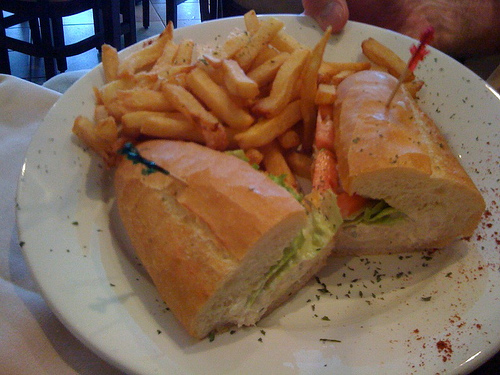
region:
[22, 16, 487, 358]
a sandwich on a plate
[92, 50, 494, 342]
a sandwich cut in half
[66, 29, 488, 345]
french fries next to a sandwich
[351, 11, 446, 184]
a colored toothpick in a sandwich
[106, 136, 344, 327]
lettuce inside of a sandwich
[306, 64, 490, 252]
slices of tomato in a sandwich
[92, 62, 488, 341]
a small baguette cut in half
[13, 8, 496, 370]
a white plate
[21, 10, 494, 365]
a plate with sprinkled herbs and spices on it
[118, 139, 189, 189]
blue plastic on toothpick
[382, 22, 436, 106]
red plastic on toothpick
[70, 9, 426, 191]
french fries on the plate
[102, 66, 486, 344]
sandwich cut in half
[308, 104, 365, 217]
tomatoes on the sandwich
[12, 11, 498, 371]
round white lunch plate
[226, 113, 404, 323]
lettuce on the sandwich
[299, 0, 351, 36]
thumb holding the plate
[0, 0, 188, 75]
legs of chairs behind plate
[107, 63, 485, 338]
white bread sandwich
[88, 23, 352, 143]
french fries on the plate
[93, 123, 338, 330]
sandwich on the plate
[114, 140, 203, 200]
toothpick stuck in a sandwich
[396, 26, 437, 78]
red tag on a toothpick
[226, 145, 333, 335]
lettuce inside of a sandwich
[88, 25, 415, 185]
french fries on a plate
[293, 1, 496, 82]
person holding a plate of food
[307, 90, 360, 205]
tomato on the sandwich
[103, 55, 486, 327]
Sandwich and french fries on a plate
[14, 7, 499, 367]
Sandwich and fries on a white plate.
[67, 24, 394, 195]
Golden french fries on the side of a plate.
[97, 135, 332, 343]
Sandwich halve on white bread.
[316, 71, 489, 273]
Lettuce and tomato on bread.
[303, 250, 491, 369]
Seasoning and garnish sprinkled on a white plate.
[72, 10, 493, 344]
Meal with french friend and a sandwich on white bread.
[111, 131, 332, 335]
Sandwich with turkey and lettuce.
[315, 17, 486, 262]
Toothpick with red top holding sandwich together.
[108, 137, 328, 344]
Toothpick with blue top stuck in sandwich.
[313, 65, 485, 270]
Red tomato slice hanging off bread.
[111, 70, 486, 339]
sandwich cut in half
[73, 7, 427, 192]
pile of french fries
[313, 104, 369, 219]
slice of tomato on sandwich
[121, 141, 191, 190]
blue toothpick on a sandwich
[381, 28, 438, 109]
red toothpick stuck in a snadwich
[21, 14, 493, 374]
plate with seasoning sprinkled on it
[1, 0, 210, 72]
chairs on floor in restaurant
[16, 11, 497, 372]
plate full of food from restaurant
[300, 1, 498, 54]
hand that is holding plate of food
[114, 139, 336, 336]
half of a sub sandwich